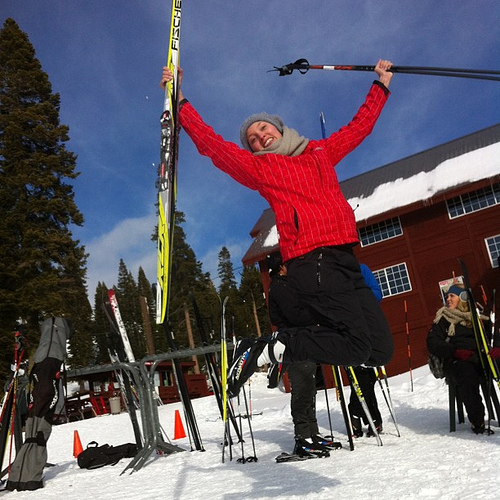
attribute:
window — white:
[373, 257, 413, 297]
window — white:
[356, 225, 403, 243]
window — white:
[443, 180, 498, 217]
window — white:
[483, 236, 497, 265]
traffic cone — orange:
[172, 411, 189, 438]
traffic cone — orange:
[71, 424, 83, 453]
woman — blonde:
[145, 86, 396, 456]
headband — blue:
[443, 274, 469, 300]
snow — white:
[47, 369, 494, 499]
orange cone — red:
[69, 428, 87, 465]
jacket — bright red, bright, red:
[180, 82, 395, 260]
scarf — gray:
[433, 302, 468, 333]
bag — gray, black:
[7, 310, 75, 495]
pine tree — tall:
[1, 12, 101, 408]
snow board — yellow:
[152, 22, 182, 338]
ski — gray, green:
[0, 303, 88, 498]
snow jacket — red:
[177, 77, 392, 262]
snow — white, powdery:
[61, 447, 493, 495]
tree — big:
[7, 19, 78, 291]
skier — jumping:
[166, 42, 413, 399]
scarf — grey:
[261, 113, 305, 165]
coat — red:
[170, 77, 390, 260]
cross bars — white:
[367, 261, 411, 299]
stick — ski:
[246, 22, 461, 98]